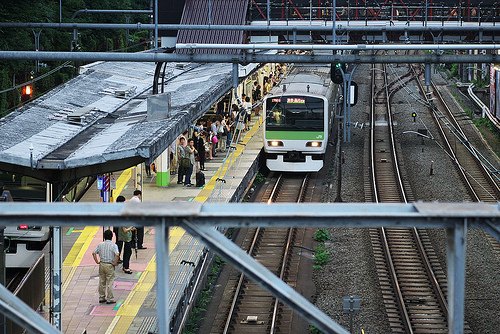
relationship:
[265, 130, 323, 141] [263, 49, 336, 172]
stripe on train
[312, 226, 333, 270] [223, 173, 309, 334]
weeds along train tracks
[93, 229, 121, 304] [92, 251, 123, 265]
man has hands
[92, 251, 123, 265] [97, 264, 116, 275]
hands on hips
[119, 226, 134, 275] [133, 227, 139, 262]
woman holding umbrella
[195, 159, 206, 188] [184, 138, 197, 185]
rolling bag in front of man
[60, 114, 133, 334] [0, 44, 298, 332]
line on platform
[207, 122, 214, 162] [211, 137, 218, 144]
woman holding purse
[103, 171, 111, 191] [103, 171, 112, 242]
stripes on pole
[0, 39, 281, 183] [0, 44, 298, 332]
roof above platform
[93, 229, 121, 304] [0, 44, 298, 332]
man on platform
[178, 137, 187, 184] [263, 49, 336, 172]
person waiting for train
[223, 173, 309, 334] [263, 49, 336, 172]
train tracks in front of train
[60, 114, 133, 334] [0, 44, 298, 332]
line at platform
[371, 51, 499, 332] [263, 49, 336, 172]
train tracks beside train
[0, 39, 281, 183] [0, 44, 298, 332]
roof of platform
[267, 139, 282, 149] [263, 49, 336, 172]
light on train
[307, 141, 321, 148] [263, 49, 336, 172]
light on train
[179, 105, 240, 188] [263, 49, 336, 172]
people waiting for train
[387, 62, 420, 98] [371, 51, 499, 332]
curve in train tracks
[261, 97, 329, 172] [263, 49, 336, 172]
front of train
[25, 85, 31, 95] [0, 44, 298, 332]
lamp near platform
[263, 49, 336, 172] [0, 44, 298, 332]
train at platform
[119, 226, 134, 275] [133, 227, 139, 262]
person holding umbrella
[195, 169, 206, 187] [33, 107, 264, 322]
suitcase on ground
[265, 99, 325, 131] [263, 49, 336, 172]
windshield on train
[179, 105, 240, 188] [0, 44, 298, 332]
people at platform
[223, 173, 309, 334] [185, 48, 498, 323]
train tracks on ground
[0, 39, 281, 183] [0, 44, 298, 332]
roof over platform